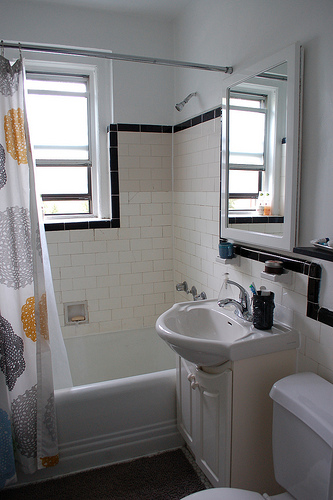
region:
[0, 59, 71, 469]
grey orang and white shower curtain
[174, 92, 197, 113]
silver metal shower head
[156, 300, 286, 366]
white ceramic kitchen sink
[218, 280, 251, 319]
silver metal sink faucet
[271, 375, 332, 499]
white ceramic toilet tank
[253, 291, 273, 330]
black toothbrush holder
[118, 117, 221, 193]
ivory ceramic bathroom tiles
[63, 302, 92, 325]
ivory soap holder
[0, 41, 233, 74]
silver metal shower curtain rod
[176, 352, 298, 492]
white wooden bathroom cabinet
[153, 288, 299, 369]
white clean handwash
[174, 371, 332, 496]
part of a white clean toilet in a bathroom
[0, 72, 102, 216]
white big window in the wall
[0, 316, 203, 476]
white clean tub in the floor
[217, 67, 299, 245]
clean mirror above the handwash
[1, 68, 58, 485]
white shower curtains with circles of colors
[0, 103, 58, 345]
two yellow circles in the white shower curtain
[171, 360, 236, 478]
two little doors under the white handwash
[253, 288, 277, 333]
black can for tooth brushes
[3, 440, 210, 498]
black bath mat in the floor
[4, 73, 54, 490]
hanging shower curtain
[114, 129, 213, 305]
white subway tiles in bathtub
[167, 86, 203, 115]
silver shower head faucet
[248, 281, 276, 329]
black toothbrush holder on sink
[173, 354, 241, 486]
white cabinets under sink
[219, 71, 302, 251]
white framed mirrored medicine cabinet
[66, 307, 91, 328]
orange bar of soap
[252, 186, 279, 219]
two bottles of bath wash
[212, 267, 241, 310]
soap dispensor on sink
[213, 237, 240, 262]
blue cup on bathroom ledge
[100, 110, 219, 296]
the wall is tiled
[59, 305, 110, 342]
soap in soap dispenser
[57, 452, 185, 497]
a rug on the floor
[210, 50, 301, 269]
mirror frame is white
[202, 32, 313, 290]
the mirror on the wall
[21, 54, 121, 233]
the window is closed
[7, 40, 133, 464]
the shower curtain on the side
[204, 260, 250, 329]
the faucet is silver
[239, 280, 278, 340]
toothbrushes in a mug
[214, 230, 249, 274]
a cup under the mirror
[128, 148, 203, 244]
The shower is made of tile.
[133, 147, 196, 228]
The tile is white and off white.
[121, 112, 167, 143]
The tile has black tile as trim.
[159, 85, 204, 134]
A shower head.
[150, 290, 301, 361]
A sink.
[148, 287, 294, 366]
The sink is white.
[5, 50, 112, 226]
A window is in the shower.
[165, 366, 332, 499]
Toilet is in the lower right.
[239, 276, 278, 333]
A black cup.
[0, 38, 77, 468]
A shower curtain.